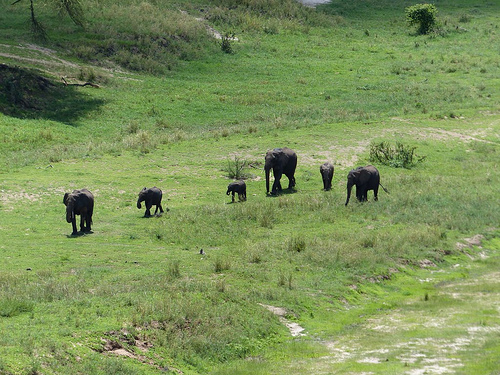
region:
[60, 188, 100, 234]
it is an elephant walking in the grass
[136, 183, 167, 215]
a baby elephant walking in the grass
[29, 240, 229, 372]
grass is on the ground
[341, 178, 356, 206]
the trunk of the horse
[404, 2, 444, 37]
a bush in the background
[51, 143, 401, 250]
a group of elephants walking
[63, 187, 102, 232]
a dark grey elephant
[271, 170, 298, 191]
it is the legs of the elephant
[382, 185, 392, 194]
the tail of the elephant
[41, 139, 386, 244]
elephants walking in a pack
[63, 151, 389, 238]
A herd of elephants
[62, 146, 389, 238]
The elephants are grey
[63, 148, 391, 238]
The elephants are walking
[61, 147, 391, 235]
The elephants are different sizes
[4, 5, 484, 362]
Short green grass and small bushes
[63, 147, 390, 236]
The elephants are on grass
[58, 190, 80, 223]
The elephant has large tusks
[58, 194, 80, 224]
The tusks are white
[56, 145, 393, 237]
There are six elephants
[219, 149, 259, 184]
Bush without leaves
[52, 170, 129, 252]
the elephant is walking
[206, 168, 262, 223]
the elephant is walking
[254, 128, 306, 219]
the elephant is walking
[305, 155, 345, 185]
the elephant is walking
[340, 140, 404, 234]
the elephant is walking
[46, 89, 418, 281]
the elephants in the wild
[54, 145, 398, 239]
Group of six elephants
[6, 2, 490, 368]
Green grass with a few barren patches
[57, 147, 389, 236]
Three adults and three baby elephants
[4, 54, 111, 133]
Shadow of tree on ground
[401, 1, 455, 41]
Small sized green tree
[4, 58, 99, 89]
Bare fallen tree branch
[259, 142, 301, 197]
Large elephant with trunk down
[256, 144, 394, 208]
Small elephant walking between two big elephants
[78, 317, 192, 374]
Eroded piece of dirt with grass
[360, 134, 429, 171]
Small green bush with leaves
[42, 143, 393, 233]
a herd of elephants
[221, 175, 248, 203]
a baby elephant on the grass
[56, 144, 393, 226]
six elephants walking on grass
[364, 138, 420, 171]
a shrub on the grass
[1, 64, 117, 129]
a shadow of a tree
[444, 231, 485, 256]
rocks in the ground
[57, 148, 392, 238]
a herd of six elephants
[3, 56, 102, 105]
a branch on the ground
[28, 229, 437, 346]
patches of overgrown grass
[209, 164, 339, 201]
two young elephants walking in the back